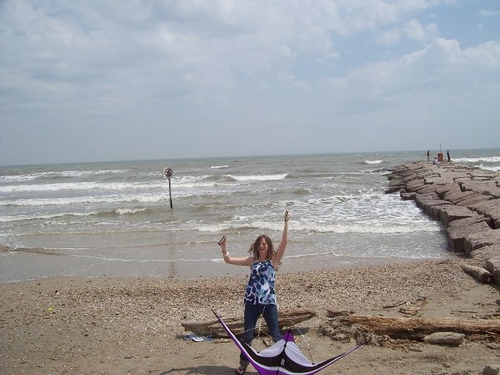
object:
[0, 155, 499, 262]
wave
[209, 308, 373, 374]
kite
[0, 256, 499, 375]
ground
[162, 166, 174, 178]
sign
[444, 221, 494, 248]
rock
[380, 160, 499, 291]
jetty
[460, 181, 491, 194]
stone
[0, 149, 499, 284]
water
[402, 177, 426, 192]
stone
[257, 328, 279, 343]
string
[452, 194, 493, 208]
stone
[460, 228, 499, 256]
stone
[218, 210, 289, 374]
woman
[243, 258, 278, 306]
pattern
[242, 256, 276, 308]
shirt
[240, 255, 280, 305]
print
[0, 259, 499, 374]
beach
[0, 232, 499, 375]
shore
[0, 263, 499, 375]
sand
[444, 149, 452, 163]
person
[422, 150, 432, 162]
person